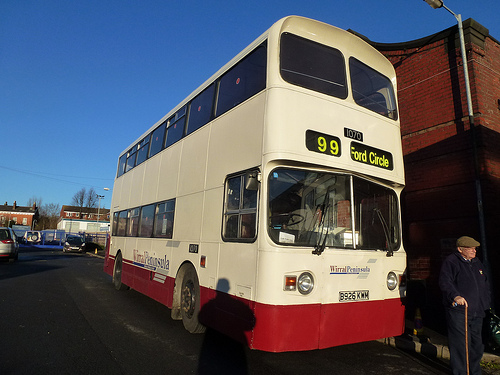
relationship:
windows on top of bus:
[112, 25, 398, 179] [73, 19, 424, 354]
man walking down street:
[435, 233, 497, 373] [344, 346, 446, 372]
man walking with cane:
[435, 233, 497, 373] [450, 295, 476, 373]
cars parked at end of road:
[20, 224, 80, 247] [10, 249, 92, 273]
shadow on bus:
[197, 281, 266, 372] [101, 24, 412, 352]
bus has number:
[101, 24, 412, 352] [309, 129, 339, 159]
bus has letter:
[101, 24, 412, 352] [348, 143, 355, 160]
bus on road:
[101, 24, 412, 352] [0, 238, 450, 375]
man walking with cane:
[435, 233, 497, 373] [445, 295, 472, 373]